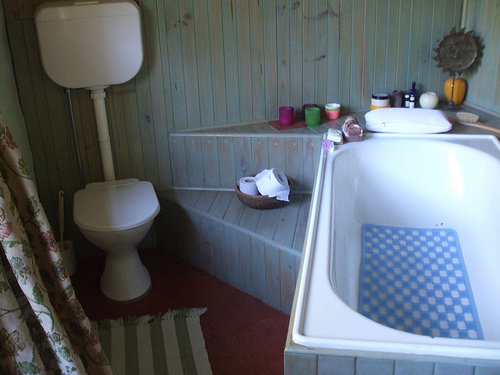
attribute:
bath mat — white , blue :
[353, 218, 485, 344]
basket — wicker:
[228, 167, 297, 212]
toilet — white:
[59, 162, 179, 300]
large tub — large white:
[281, 129, 498, 374]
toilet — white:
[30, 2, 165, 306]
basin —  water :
[20, 0, 166, 96]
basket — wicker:
[228, 162, 299, 212]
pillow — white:
[365, 103, 462, 131]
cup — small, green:
[296, 103, 323, 129]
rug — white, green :
[87, 307, 217, 373]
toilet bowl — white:
[70, 178, 162, 303]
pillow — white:
[364, 105, 452, 130]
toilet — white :
[66, 171, 171, 308]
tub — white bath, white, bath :
[292, 130, 499, 362]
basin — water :
[29, 11, 164, 97]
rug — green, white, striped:
[82, 314, 237, 364]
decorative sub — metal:
[431, 25, 485, 77]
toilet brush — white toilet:
[42, 185, 83, 290]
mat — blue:
[357, 223, 486, 348]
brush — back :
[434, 26, 484, 123]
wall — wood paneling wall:
[196, 20, 369, 80]